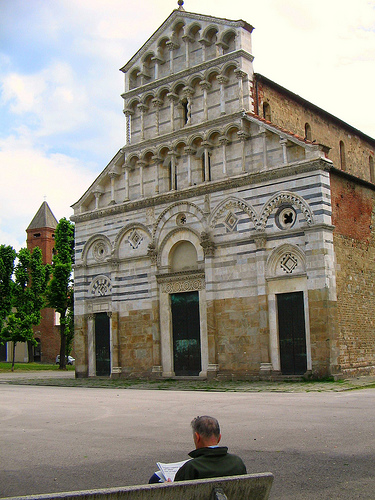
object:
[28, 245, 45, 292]
leaves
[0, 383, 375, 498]
pavement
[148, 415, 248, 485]
man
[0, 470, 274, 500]
bench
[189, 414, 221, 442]
hair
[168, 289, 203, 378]
door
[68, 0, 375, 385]
building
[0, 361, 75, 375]
grass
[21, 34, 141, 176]
sky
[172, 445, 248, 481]
jacket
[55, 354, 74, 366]
vehicle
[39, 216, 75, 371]
tree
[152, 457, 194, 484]
paper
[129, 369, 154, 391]
weed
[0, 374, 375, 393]
walkway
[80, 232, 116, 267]
window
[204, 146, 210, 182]
pillar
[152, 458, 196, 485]
newspaper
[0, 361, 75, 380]
yard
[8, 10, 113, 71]
cloud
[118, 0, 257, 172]
design